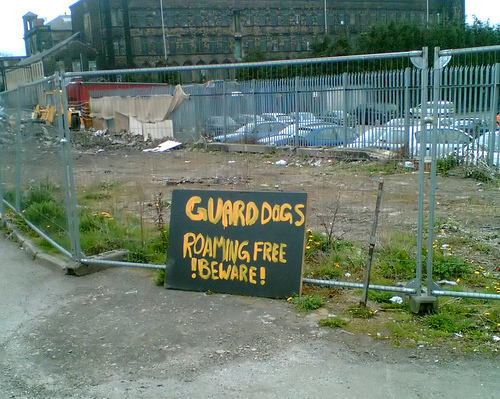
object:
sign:
[162, 189, 309, 300]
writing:
[182, 194, 304, 286]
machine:
[33, 90, 87, 131]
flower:
[28, 177, 36, 194]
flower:
[305, 228, 323, 253]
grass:
[2, 185, 499, 345]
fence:
[0, 44, 500, 301]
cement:
[0, 229, 499, 397]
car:
[327, 125, 473, 160]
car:
[200, 116, 241, 136]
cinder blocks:
[409, 292, 439, 315]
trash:
[388, 292, 403, 305]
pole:
[359, 177, 383, 308]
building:
[65, 81, 166, 133]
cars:
[257, 125, 357, 150]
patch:
[82, 179, 111, 199]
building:
[20, 0, 466, 84]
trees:
[230, 7, 500, 113]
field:
[1, 106, 500, 398]